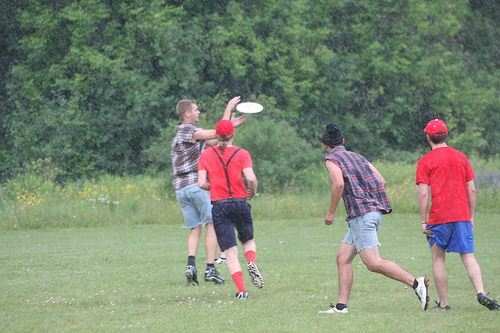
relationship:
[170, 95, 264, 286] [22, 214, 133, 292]
man in field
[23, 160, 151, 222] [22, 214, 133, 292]
wildflower by field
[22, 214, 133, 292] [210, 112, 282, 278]
field has man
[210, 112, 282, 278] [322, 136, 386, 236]
man in shirt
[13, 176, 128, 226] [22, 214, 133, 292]
flowers on field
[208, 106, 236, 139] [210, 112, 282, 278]
cap on man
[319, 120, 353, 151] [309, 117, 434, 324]
head of boy